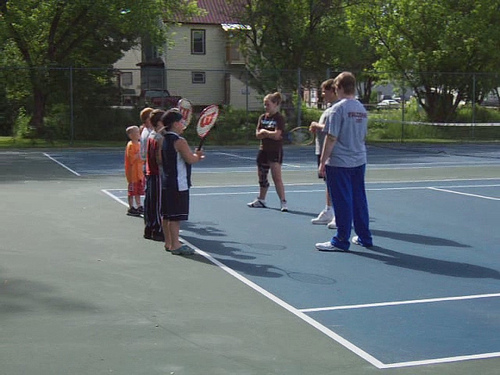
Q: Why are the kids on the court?
A: To learn tennis.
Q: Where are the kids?
A: On a court.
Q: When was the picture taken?
A: Daytime.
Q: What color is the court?
A: Blue.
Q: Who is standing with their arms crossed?
A: The girl.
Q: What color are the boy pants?
A: Blue.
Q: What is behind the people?
A: A house.